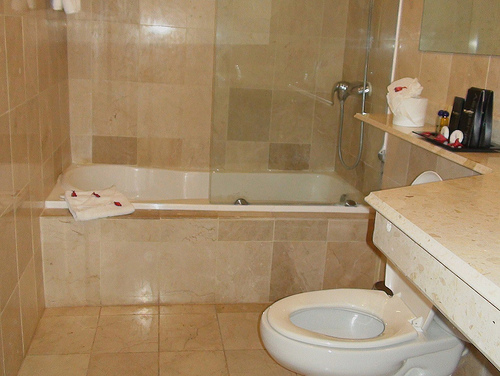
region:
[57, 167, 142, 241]
Folded towel on side of tub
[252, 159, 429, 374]
White toilet with lid up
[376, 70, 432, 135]
Roll of toilet paper sitting on shelf above toilet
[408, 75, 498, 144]
Black tray of toiletries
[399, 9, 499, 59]
Wall mirror above toilet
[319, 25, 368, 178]
Handheld shower head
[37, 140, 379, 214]
White bath tub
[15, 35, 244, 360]
Beige bathroom tile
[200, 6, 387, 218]
Clear glass shower door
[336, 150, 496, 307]
Beige countertop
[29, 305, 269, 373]
a light brown tile floor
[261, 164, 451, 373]
a white toilet in a bathroom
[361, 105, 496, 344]
a bathroom counter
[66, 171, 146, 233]
a towel on the edge of a bathtub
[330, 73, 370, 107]
the faucet in a shower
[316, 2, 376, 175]
the hose of a hand held shower head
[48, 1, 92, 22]
a towel hanging in a shower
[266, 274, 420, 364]
the seat of a toilet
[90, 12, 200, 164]
brown tile in a shower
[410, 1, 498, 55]
a mirror on a wall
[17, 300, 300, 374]
Tan tiled floor of the bathroom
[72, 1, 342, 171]
Tan tiled wall behind the white tub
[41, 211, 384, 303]
Tan tiled exterior of the tub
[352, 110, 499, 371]
Long counter next to and behind the white toilet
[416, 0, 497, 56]
Mirror on the wall above the counter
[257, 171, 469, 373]
White toilet with an open lid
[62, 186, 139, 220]
White towel with red adornments laying on the tub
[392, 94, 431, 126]
Roll of toilet paper sitting on the counter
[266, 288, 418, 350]
Oval seat on the toilet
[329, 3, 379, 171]
Silver shower spray attachment on the wall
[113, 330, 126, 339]
part of a floor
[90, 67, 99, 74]
section of a wall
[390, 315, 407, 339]
part of a toilet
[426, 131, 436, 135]
edge of a shelf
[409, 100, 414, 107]
part of a tissue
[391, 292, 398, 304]
part of a toilet seat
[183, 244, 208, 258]
wall of a bath tab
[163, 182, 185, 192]
inside of a bath tab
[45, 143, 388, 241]
bathtub in a bathroom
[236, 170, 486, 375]
toilet is white and plastic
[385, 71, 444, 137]
toilet paper above toilet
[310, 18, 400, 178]
silver chromed shower fixture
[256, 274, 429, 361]
white plastic toilet seat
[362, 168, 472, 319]
white plastic toilet lid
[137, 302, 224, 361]
tile on a floor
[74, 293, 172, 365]
tile on a floor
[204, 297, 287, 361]
tile on a floor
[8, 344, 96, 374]
tile on a floor